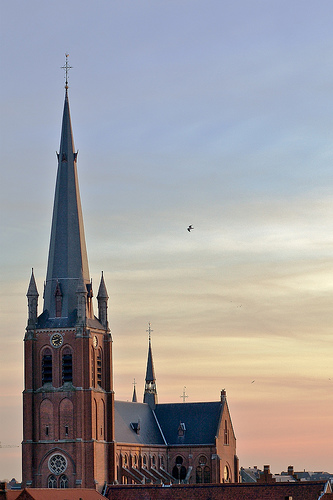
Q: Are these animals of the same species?
A: Yes, all the animals are birds.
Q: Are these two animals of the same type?
A: Yes, all the animals are birds.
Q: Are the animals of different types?
A: No, all the animals are birds.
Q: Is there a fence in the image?
A: No, there are no fences.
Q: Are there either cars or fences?
A: No, there are no fences or cars.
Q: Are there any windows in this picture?
A: Yes, there are windows.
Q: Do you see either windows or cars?
A: Yes, there are windows.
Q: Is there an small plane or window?
A: Yes, there are small windows.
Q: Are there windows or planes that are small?
A: Yes, the windows are small.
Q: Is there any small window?
A: Yes, there are small windows.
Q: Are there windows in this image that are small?
A: Yes, there are windows that are small.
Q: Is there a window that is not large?
A: Yes, there are small windows.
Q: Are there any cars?
A: No, there are no cars.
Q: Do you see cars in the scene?
A: No, there are no cars.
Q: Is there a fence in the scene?
A: No, there are no fences.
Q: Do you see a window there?
A: Yes, there are windows.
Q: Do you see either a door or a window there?
A: Yes, there are windows.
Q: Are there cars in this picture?
A: No, there are no cars.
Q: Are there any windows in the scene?
A: Yes, there is a window.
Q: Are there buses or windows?
A: Yes, there is a window.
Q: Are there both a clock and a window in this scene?
A: Yes, there are both a window and a clock.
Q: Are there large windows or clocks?
A: Yes, there is a large window.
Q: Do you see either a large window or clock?
A: Yes, there is a large window.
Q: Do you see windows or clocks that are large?
A: Yes, the window is large.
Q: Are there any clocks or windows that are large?
A: Yes, the window is large.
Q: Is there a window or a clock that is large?
A: Yes, the window is large.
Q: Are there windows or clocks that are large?
A: Yes, the window is large.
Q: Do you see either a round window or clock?
A: Yes, there is a round window.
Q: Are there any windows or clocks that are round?
A: Yes, the window is round.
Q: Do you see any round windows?
A: Yes, there is a round window.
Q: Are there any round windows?
A: Yes, there is a round window.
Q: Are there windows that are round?
A: Yes, there is a window that is round.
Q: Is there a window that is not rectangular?
A: Yes, there is a round window.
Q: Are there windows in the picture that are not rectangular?
A: Yes, there is a round window.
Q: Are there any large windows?
A: Yes, there is a large window.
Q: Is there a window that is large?
A: Yes, there is a window that is large.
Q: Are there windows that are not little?
A: Yes, there is a large window.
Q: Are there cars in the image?
A: No, there are no cars.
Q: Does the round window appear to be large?
A: Yes, the window is large.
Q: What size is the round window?
A: The window is large.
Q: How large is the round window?
A: The window is large.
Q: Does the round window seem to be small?
A: No, the window is large.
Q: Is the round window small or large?
A: The window is large.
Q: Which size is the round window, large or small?
A: The window is large.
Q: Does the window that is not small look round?
A: Yes, the window is round.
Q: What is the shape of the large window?
A: The window is round.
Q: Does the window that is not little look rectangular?
A: No, the window is round.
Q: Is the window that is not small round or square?
A: The window is round.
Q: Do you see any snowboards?
A: No, there are no snowboards.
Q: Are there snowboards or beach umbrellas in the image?
A: No, there are no snowboards or beach umbrellas.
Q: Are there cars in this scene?
A: No, there are no cars.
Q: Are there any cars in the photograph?
A: No, there are no cars.